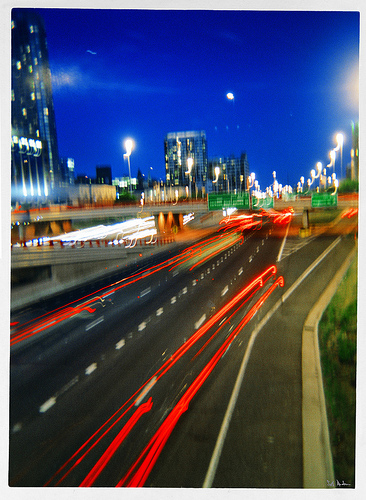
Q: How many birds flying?
A: Zero.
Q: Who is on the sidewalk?
A: No one.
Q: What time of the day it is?
A: Evening.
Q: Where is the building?
A: Along the interstate.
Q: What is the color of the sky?
A: Blue.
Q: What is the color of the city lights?
A: Red and white.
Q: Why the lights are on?
A: It's night time.